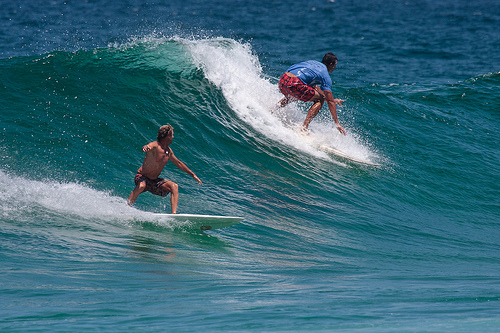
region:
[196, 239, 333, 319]
the water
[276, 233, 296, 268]
the water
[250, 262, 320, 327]
the water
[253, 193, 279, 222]
the water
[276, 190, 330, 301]
the water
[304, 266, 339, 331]
the water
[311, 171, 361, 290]
the water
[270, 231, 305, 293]
the water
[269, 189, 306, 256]
the water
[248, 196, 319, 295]
the water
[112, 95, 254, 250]
Man is surfing in the ocean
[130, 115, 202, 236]
The surfer is not wearing a shirt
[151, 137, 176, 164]
The man is wearing a necklace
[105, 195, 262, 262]
The surfboard is white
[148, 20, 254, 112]
There is a whitecap on the top of the wave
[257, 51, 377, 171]
the man is surfing on the wave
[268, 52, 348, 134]
He is wearing blue and red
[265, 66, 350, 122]
Surfer wearing plaid bathing suit bottoms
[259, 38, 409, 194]
The man is reaching toward his surfboard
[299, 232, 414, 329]
The water is very blue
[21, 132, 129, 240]
splash of beach water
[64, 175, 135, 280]
splash of beach water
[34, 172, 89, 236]
splash of beach water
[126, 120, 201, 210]
man riding long surfboard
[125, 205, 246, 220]
long white surfboard in ocean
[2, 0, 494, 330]
blue ocean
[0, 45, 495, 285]
wave in ocean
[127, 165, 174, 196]
dark colored shorts on man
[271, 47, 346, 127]
man surfing wave on surfboard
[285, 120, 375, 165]
long white surfboard in wave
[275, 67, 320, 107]
red and black checkered shorts on man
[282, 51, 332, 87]
blue tshirt on man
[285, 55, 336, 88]
soaking wet tshirt on man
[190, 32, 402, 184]
a surfer trying to catch a wave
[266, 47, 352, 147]
the surfer is goofy footed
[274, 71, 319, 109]
the man is wearing plaid jams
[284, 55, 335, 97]
blue shirt is on the man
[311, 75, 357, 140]
the hands are balancing the ride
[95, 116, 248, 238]
the surfer is catching a wave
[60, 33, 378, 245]
the two surfers are catching the same wave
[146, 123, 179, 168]
the man has a shiny object on his chest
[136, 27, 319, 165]
the wave is beginning to break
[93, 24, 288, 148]
the wave is forming a tube